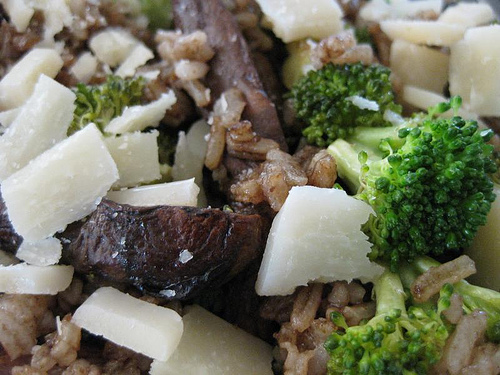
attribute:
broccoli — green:
[261, 55, 491, 374]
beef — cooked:
[89, 203, 250, 300]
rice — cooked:
[170, 84, 287, 188]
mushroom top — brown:
[98, 217, 204, 283]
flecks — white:
[347, 80, 412, 135]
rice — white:
[306, 28, 372, 68]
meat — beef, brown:
[188, 25, 273, 128]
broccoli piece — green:
[325, 93, 499, 271]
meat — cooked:
[213, 22, 258, 69]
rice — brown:
[165, 34, 223, 97]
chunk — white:
[348, 88, 380, 110]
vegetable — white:
[253, 186, 385, 301]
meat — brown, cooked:
[58, 196, 268, 301]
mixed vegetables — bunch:
[45, 35, 465, 337]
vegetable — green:
[346, 122, 474, 247]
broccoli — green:
[285, 59, 493, 374]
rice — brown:
[167, 29, 214, 106]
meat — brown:
[180, 2, 282, 122]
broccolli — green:
[296, 58, 394, 147]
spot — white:
[174, 248, 193, 264]